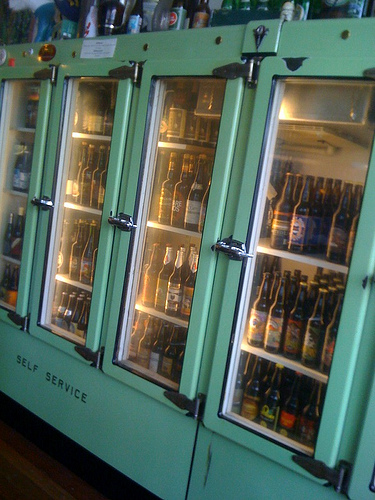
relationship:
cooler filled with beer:
[0, 17, 373, 498] [1, 84, 361, 444]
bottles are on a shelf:
[270, 172, 359, 264] [257, 236, 349, 275]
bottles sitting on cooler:
[0, 0, 371, 42] [0, 17, 373, 498]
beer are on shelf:
[1, 84, 361, 444] [257, 236, 349, 275]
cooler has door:
[0, 17, 373, 498] [101, 72, 246, 421]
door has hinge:
[101, 72, 246, 421] [246, 58, 255, 85]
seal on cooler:
[38, 44, 59, 62] [0, 17, 373, 498]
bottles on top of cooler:
[0, 0, 371, 42] [0, 17, 373, 498]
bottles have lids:
[270, 172, 359, 264] [285, 171, 362, 191]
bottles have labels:
[270, 172, 359, 264] [272, 210, 354, 254]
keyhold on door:
[110, 209, 115, 218] [101, 72, 246, 421]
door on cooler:
[101, 72, 246, 421] [0, 17, 373, 498]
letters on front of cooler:
[17, 355, 89, 405] [0, 17, 373, 498]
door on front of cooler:
[101, 72, 246, 421] [0, 17, 373, 498]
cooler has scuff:
[0, 17, 373, 498] [200, 433, 219, 490]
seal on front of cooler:
[38, 44, 59, 62] [0, 17, 373, 498]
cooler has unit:
[0, 17, 373, 498] [192, 82, 373, 154]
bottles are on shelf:
[270, 172, 359, 264] [257, 236, 349, 275]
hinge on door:
[246, 58, 255, 85] [101, 72, 246, 421]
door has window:
[101, 72, 246, 421] [109, 72, 232, 395]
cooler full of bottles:
[0, 17, 373, 498] [270, 172, 359, 264]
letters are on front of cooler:
[17, 355, 89, 405] [0, 17, 373, 498]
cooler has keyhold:
[0, 17, 373, 498] [110, 209, 115, 218]